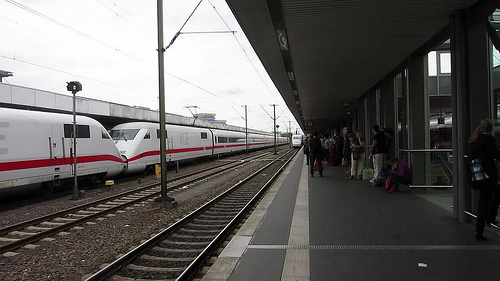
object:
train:
[290, 133, 303, 147]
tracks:
[82, 147, 298, 280]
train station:
[200, 1, 498, 280]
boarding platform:
[202, 144, 497, 280]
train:
[1, 107, 124, 204]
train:
[107, 122, 290, 172]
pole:
[158, 0, 164, 200]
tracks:
[0, 144, 287, 256]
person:
[384, 159, 411, 192]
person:
[306, 134, 324, 177]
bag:
[311, 159, 321, 171]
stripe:
[281, 152, 311, 281]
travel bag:
[362, 168, 373, 182]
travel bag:
[384, 176, 393, 192]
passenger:
[367, 125, 392, 185]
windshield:
[109, 129, 139, 140]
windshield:
[293, 137, 301, 140]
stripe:
[201, 144, 304, 278]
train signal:
[65, 81, 83, 96]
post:
[67, 82, 80, 201]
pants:
[372, 154, 383, 179]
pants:
[351, 152, 364, 174]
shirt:
[389, 159, 407, 177]